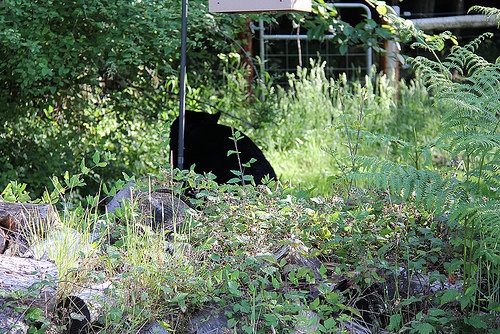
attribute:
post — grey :
[382, 3, 498, 106]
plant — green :
[378, 34, 499, 181]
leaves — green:
[173, 205, 372, 317]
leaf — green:
[44, 102, 57, 117]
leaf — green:
[104, 96, 114, 105]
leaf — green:
[116, 110, 128, 117]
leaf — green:
[121, 85, 136, 95]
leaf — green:
[111, 132, 126, 140]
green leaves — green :
[0, 3, 235, 193]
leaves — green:
[4, 3, 158, 207]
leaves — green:
[273, 1, 425, 52]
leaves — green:
[176, 172, 424, 332]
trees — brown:
[3, 7, 498, 164]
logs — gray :
[1, 256, 105, 309]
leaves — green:
[3, 5, 239, 61]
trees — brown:
[4, 4, 281, 163]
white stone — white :
[98, 186, 196, 239]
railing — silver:
[372, 10, 499, 32]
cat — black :
[153, 107, 323, 190]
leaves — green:
[7, 6, 52, 36]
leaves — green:
[6, 49, 55, 94]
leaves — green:
[70, 100, 102, 155]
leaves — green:
[7, 107, 57, 183]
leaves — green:
[189, 3, 376, 55]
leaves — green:
[122, 20, 157, 64]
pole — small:
[177, 0, 188, 166]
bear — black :
[162, 114, 275, 195]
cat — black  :
[153, 104, 321, 206]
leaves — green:
[75, 83, 127, 150]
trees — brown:
[64, 36, 276, 297]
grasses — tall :
[299, 118, 407, 200]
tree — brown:
[2, 0, 411, 203]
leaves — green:
[2, 0, 404, 201]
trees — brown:
[140, 65, 162, 88]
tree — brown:
[138, 63, 163, 90]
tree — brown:
[383, 38, 397, 91]